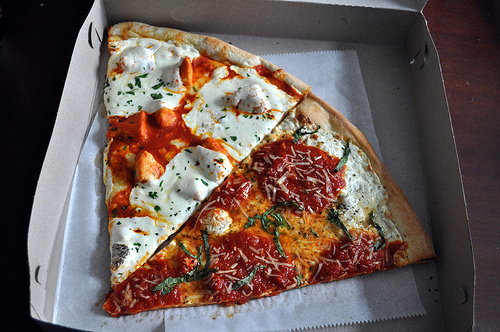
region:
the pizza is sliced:
[125, 42, 332, 313]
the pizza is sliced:
[128, 65, 281, 232]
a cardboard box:
[0, 4, 472, 330]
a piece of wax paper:
[53, 42, 425, 328]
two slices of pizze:
[108, 22, 428, 294]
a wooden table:
[11, 5, 487, 328]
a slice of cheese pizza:
[86, 31, 296, 268]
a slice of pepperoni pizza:
[123, 120, 411, 310]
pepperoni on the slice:
[202, 231, 305, 293]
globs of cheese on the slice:
[110, 38, 193, 128]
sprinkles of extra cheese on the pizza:
[134, 153, 348, 301]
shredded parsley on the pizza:
[159, 148, 359, 307]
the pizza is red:
[200, 200, 316, 303]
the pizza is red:
[220, 190, 402, 310]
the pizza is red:
[193, 150, 290, 295]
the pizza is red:
[229, 160, 307, 284]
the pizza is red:
[203, 220, 251, 304]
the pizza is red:
[196, 167, 257, 274]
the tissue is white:
[332, 303, 343, 314]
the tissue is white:
[290, 304, 300, 326]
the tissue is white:
[305, 306, 317, 328]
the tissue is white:
[320, 294, 333, 329]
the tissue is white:
[312, 310, 317, 327]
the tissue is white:
[327, 315, 336, 330]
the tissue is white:
[324, 304, 331, 323]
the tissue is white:
[298, 307, 306, 319]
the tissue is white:
[301, 303, 315, 320]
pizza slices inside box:
[25, 2, 466, 328]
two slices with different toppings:
[85, 21, 440, 316]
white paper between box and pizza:
[47, 15, 427, 325]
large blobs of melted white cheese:
[91, 17, 297, 248]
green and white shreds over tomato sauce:
[100, 85, 430, 315]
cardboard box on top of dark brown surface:
[10, 10, 491, 317]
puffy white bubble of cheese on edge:
[177, 197, 244, 242]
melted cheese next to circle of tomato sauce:
[260, 132, 380, 222]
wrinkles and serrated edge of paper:
[167, 280, 372, 326]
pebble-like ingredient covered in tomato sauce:
[125, 50, 205, 180]